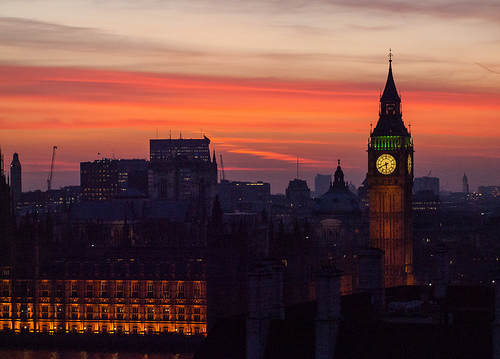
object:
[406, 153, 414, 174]
clock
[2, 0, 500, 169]
sky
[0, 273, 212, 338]
light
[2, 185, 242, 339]
building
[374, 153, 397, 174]
clock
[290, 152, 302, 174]
pole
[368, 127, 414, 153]
lights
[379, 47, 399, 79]
rod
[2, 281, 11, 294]
window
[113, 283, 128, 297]
window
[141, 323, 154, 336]
window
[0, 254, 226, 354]
wall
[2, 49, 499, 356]
building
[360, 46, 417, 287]
clock tower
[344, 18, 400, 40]
clouds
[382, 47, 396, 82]
tower top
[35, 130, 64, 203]
crane head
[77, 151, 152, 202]
building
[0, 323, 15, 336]
windows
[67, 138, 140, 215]
lights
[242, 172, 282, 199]
lights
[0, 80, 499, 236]
city skyline